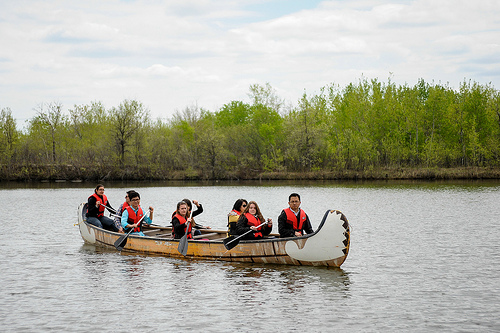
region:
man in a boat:
[280, 183, 320, 229]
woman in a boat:
[246, 200, 258, 240]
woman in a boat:
[223, 193, 245, 224]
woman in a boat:
[170, 200, 200, 242]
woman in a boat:
[121, 191, 158, 224]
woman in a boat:
[86, 177, 109, 222]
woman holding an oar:
[238, 197, 283, 247]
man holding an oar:
[105, 195, 157, 255]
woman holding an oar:
[80, 182, 111, 219]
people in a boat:
[72, 169, 375, 280]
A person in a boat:
[288, 189, 315, 236]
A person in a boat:
[243, 200, 270, 237]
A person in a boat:
[224, 191, 244, 230]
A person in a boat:
[165, 201, 204, 241]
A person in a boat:
[120, 191, 153, 234]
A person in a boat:
[82, 182, 109, 235]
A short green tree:
[318, 79, 370, 162]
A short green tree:
[368, 81, 408, 166]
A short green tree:
[420, 84, 477, 171]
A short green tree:
[251, 93, 286, 160]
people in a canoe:
[68, 180, 368, 276]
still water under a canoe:
[386, 190, 485, 300]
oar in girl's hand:
[179, 212, 191, 262]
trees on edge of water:
[217, 88, 470, 164]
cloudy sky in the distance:
[38, 22, 485, 91]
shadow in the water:
[75, 238, 117, 260]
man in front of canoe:
[277, 190, 315, 250]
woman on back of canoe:
[80, 182, 116, 227]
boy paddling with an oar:
[104, 192, 157, 246]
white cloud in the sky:
[107, 59, 187, 88]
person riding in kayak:
[278, 194, 312, 234]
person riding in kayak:
[235, 199, 273, 239]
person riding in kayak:
[227, 197, 246, 234]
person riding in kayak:
[172, 202, 192, 239]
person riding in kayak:
[180, 196, 202, 231]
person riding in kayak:
[120, 194, 155, 236]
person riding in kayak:
[118, 192, 142, 224]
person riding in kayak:
[88, 185, 113, 227]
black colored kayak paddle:
[226, 219, 266, 249]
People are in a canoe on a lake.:
[60, 153, 393, 303]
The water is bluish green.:
[376, 192, 497, 327]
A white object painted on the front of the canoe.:
[281, 203, 346, 266]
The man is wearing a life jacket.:
[276, 190, 309, 235]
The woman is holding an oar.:
[220, 218, 273, 250]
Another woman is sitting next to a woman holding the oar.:
[227, 193, 247, 220]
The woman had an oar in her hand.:
[172, 196, 202, 255]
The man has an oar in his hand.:
[111, 190, 152, 253]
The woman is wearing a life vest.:
[85, 191, 110, 217]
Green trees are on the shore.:
[1, 84, 499, 160]